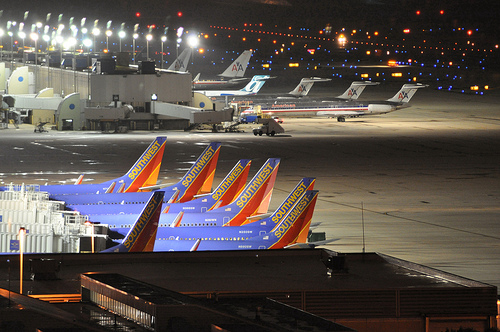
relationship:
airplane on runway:
[267, 85, 439, 134] [384, 140, 441, 210]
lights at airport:
[278, 41, 417, 76] [367, 140, 440, 212]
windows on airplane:
[180, 218, 220, 231] [80, 139, 307, 248]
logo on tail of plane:
[343, 84, 360, 101] [231, 74, 383, 123]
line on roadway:
[338, 204, 498, 212] [330, 142, 479, 278]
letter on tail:
[273, 221, 286, 242] [251, 180, 327, 247]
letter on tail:
[269, 221, 294, 240] [261, 178, 329, 270]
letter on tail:
[273, 230, 282, 239] [269, 178, 326, 267]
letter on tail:
[280, 213, 297, 242] [262, 180, 329, 259]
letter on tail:
[286, 210, 296, 225] [265, 177, 337, 245]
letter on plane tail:
[294, 207, 321, 231] [238, 176, 319, 230]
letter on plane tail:
[299, 198, 308, 207] [268, 177, 324, 247]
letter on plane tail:
[290, 204, 300, 216] [268, 168, 326, 246]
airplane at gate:
[235, 80, 432, 124] [4, 46, 211, 126]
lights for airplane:
[2, 19, 203, 55] [235, 80, 432, 124]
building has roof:
[2, 239, 498, 329] [2, 244, 492, 314]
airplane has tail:
[235, 80, 432, 124] [386, 81, 422, 104]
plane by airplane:
[250, 108, 290, 138] [235, 80, 432, 124]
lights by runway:
[413, 54, 480, 92] [419, 92, 497, 106]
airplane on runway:
[102, 183, 332, 252] [19, 123, 493, 259]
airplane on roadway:
[26, 128, 186, 193] [0, 79, 500, 300]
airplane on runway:
[0, 133, 178, 194] [4, 132, 456, 244]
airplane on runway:
[97, 179, 175, 246] [19, 123, 493, 259]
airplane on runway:
[45, 140, 224, 206] [10, 128, 364, 244]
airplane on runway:
[204, 72, 340, 102] [195, 81, 495, 142]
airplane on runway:
[199, 48, 257, 77] [195, 70, 398, 117]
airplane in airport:
[0, 133, 178, 194] [4, 6, 498, 253]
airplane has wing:
[235, 80, 432, 124] [311, 109, 374, 119]